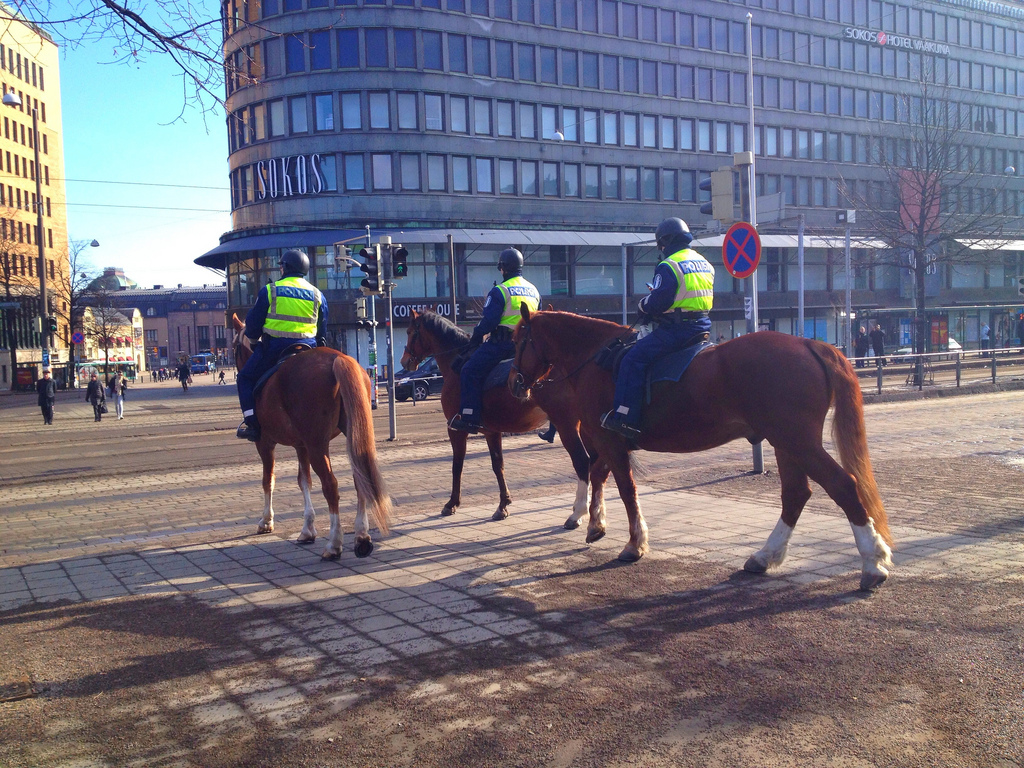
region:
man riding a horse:
[225, 253, 396, 564]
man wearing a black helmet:
[598, 217, 715, 448]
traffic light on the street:
[358, 239, 415, 443]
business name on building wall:
[248, 156, 335, 202]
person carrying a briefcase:
[81, 371, 108, 425]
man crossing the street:
[35, 370, 61, 428]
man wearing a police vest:
[232, 251, 330, 439]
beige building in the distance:
[1, 1, 74, 394]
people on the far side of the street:
[23, 358, 132, 422]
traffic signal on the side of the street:
[361, 231, 412, 301]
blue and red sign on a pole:
[722, 221, 764, 275]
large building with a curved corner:
[217, 0, 1021, 392]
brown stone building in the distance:
[0, 0, 76, 380]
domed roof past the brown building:
[81, 263, 136, 299]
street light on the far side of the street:
[2, 83, 56, 396]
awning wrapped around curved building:
[192, 214, 1021, 269]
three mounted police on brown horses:
[229, 213, 897, 597]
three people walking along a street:
[33, 371, 133, 428]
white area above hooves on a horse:
[741, 514, 888, 582]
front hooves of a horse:
[585, 522, 647, 564]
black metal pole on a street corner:
[32, 93, 61, 420]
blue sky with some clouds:
[0, 0, 236, 296]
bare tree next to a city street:
[803, 81, 1016, 383]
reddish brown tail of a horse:
[333, 350, 397, 537]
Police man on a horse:
[222, 247, 406, 570]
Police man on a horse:
[505, 219, 913, 603]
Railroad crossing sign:
[717, 217, 769, 281]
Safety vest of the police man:
[263, 271, 328, 341]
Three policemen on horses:
[218, 220, 902, 593]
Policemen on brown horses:
[231, 225, 908, 593]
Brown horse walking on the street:
[498, 301, 901, 596]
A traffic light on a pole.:
[351, 222, 418, 457]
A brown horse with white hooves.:
[500, 291, 912, 605]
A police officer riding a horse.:
[590, 202, 727, 456]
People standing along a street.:
[26, 353, 147, 430]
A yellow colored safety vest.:
[247, 277, 328, 342]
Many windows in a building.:
[213, 2, 1017, 224]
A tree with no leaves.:
[803, 63, 1018, 403]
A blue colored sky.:
[61, 73, 224, 184]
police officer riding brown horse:
[235, 227, 404, 576]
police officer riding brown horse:
[413, 240, 554, 506]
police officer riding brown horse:
[511, 200, 894, 634]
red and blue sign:
[719, 221, 767, 282]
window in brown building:
[251, 94, 294, 146]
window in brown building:
[321, 91, 370, 148]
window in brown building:
[383, 72, 422, 139]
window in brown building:
[498, 94, 546, 161]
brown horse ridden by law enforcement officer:
[510, 293, 921, 594]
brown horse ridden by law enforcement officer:
[252, 257, 421, 559]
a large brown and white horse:
[501, 304, 906, 596]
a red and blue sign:
[715, 220, 766, 279]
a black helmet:
[649, 218, 695, 250]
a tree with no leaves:
[814, 79, 1004, 409]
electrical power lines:
[1, 164, 233, 218]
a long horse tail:
[336, 354, 404, 531]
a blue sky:
[77, 67, 170, 160]